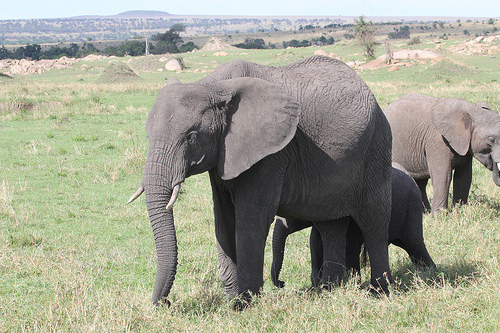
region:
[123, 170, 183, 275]
a section of an elephant trunk.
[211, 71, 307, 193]
the left ear of an elephant.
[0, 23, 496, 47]
a large mountain range.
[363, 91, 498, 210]
a baby elephant in a field.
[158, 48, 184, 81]
a large boulder in a field.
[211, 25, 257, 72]
a hill in the distance.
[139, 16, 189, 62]
a bunch of green trees.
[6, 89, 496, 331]
a field of lush green grass.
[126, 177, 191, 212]
baby elephant tusk.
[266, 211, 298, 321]
an elephant's trunkk.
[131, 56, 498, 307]
group of three grey elephants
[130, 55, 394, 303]
a big grey adult elephant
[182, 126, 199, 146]
an adult elephant's left eye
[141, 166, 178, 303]
an adult elephants trunk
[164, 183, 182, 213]
an adult elephant's left tusk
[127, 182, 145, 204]
an adult elephant's right tusk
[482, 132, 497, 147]
a baby elephant's right eye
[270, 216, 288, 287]
a baby elephant's trunk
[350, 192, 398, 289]
an adult elephant's left leg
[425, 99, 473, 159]
a baby elephant's right ear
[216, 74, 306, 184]
large gray elephant ear with sun on it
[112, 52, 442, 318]
large gray elephant with baby elephant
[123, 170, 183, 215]
two white elephant tusks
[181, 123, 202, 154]
left elephant eye with sun shining on it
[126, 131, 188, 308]
gray elephant trunk pointed downward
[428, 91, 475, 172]
right gray elephant ear with spot of mud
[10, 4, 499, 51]
skyline with mountains and green scrub brush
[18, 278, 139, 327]
dry yellow grass intermixed with green short grass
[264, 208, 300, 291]
baby elephant trunk pointed downward under mother elephant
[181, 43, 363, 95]
curved gray adult elephant back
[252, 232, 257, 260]
front leg of an elephant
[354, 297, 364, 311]
part of the grass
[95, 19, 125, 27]
section of a hilly terrain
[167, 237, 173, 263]
trunk of an elephant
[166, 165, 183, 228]
horn of an elephant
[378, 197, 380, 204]
back leg of an elephant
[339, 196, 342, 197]
body of an elephant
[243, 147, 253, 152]
ear of an elephant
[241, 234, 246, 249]
leg of an elephant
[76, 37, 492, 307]
elephants walking on grassy flat land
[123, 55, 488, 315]
adult elephant followed by younger ones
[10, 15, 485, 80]
tan mounds in back of elephants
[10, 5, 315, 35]
trees dotting distance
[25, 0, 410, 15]
hazy and pale blue sky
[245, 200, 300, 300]
small trunk under adult's body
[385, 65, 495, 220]
elephant with closed eye eating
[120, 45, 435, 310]
small elephants behind adult's rear leg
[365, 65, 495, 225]
elephant facing different directions from others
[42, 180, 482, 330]
tan and green grass under feet